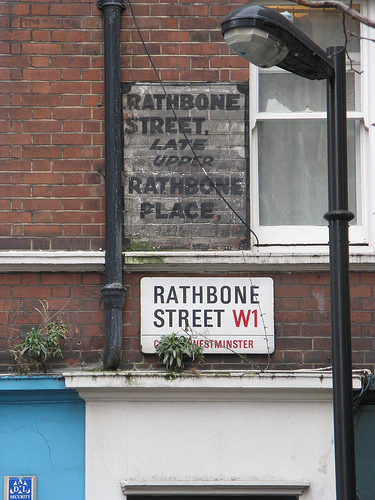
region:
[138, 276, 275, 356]
white sign with black and red writting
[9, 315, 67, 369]
a small green bush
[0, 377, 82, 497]
the wall is painted blue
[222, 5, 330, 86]
the street light is off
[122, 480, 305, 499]
an opening in the wall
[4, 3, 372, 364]
red brick wall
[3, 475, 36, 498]
a blue and white sign on the building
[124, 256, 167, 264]
green mold growing on the trim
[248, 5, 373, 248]
white framed window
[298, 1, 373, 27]
a bare tree branch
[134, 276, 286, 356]
red, white, and black sign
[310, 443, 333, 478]
black mark on the white paint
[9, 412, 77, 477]
cracks in the concrete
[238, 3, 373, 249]
window on the building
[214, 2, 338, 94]
light on the top of the pole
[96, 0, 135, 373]
black pipe running down the side of the building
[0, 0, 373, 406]
building is made of brick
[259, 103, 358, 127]
white rod on the window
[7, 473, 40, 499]
blue and white sign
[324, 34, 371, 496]
black pole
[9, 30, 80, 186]
Red color bricks of the building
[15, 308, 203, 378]
Small plant in the building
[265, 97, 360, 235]
White color frame with glass windows of the building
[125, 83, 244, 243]
Some text written in the building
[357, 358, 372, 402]
Wires near the metal pole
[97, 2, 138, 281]
Black color outlet pipe in the building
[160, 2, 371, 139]
Street light near the building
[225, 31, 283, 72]
White color glass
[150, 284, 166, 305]
The letter is black.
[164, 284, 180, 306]
The letter is black.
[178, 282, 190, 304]
The letter is black.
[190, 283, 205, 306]
The letter is black.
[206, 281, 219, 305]
The letter is black.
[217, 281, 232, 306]
The letter is black.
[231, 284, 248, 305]
The letter is black.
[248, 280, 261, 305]
The letter is black.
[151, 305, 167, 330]
The letter is black.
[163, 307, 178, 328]
The letter is black.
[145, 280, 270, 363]
words are written on a white board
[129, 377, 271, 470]
wall is white in color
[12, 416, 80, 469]
wall is blue in color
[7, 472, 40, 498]
poster is blue in color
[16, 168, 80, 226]
wall is red bricked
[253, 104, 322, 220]
window is closed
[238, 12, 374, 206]
street light beside the building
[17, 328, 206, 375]
plants on top of the building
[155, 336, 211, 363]
plants are green in color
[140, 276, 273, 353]
street sign is white, red and blue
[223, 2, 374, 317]
window is on building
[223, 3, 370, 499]
light pole is black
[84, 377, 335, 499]
wall is color white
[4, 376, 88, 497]
wall is color blue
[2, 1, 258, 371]
bricks are color red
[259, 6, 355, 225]
window has white curtain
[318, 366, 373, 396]
wire is white and blue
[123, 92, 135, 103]
r on the sign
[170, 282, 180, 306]
a on the sign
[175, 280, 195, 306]
t on the sign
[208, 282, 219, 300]
b on the sign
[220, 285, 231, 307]
o on the sign